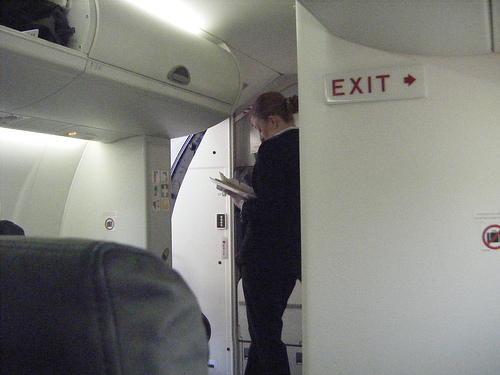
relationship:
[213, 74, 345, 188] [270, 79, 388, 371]
flight attendant leaning on a wall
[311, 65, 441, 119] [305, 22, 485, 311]
sign on a wall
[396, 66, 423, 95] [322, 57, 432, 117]
arrow on a sign